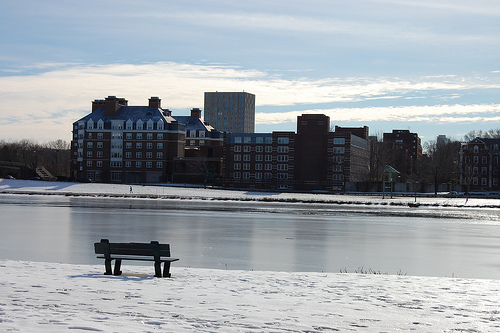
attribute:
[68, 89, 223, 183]
building — large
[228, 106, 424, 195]
building — large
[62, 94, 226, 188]
building — large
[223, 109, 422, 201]
building — large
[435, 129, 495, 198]
building — large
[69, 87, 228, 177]
building — large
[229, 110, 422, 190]
building — brick, large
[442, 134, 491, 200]
building — large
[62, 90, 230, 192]
building — large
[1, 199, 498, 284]
water — still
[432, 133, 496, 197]
building — large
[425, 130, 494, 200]
building — large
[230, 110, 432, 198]
building — large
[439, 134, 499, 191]
building — large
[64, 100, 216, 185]
building — large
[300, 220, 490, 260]
water — frozen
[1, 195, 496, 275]
river — frozen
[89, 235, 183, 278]
bench — empty, black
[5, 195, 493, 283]
body — frozen, of water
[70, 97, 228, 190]
building — dark, brick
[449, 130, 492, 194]
building — brick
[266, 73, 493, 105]
clouds — white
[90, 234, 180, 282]
bench — dark, wood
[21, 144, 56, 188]
trees — bare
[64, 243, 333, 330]
snow — white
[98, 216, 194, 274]
bench — wooden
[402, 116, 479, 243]
trees — bare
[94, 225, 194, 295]
bench — brown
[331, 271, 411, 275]
grass — brown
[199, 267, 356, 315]
snow — white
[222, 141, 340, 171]
windows — clear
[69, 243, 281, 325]
beach — snowy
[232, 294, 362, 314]
floor — snowy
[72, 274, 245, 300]
footprints — snowy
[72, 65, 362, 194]
buildings — tall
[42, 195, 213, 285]
bench — brown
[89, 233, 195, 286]
bench — brown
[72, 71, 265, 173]
buildings — brown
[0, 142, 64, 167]
trees — brown